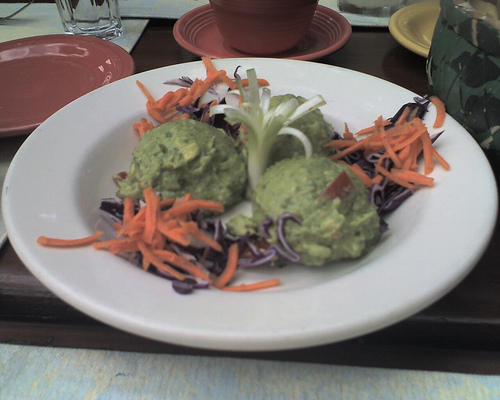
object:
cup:
[210, 0, 318, 55]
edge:
[177, 329, 337, 350]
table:
[10, 275, 498, 400]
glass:
[50, 1, 124, 41]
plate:
[19, 33, 489, 365]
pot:
[429, 0, 499, 153]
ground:
[436, 230, 455, 251]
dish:
[0, 56, 500, 356]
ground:
[316, 158, 337, 190]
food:
[35, 55, 450, 295]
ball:
[251, 153, 382, 266]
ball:
[115, 117, 249, 212]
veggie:
[38, 231, 105, 248]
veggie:
[162, 249, 206, 279]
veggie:
[428, 95, 446, 129]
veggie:
[200, 50, 236, 86]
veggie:
[353, 159, 372, 187]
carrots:
[141, 187, 160, 245]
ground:
[246, 53, 284, 73]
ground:
[275, 90, 305, 122]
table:
[348, 29, 406, 66]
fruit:
[204, 64, 323, 187]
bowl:
[206, 1, 321, 56]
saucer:
[171, 1, 350, 61]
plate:
[383, 4, 441, 57]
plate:
[0, 33, 139, 139]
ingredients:
[113, 75, 421, 285]